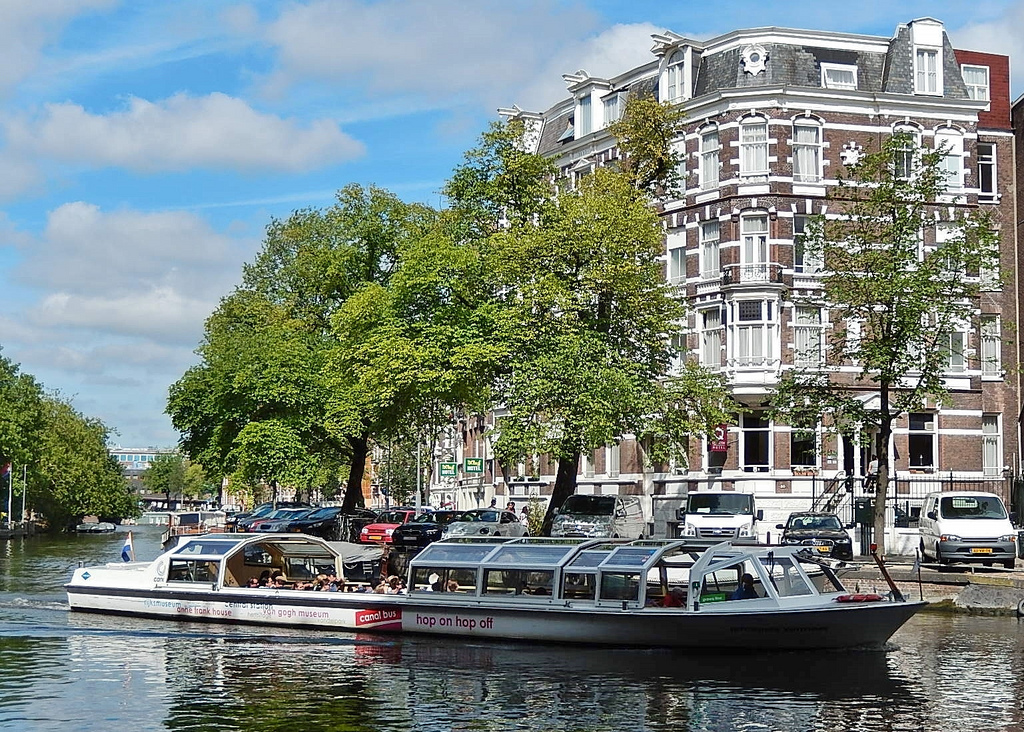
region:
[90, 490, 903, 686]
long white boat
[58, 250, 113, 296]
white clouds in blue sky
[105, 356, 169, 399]
white clouds in blue sky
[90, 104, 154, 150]
white clouds in blue sky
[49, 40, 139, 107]
white clouds in blue sky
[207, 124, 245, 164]
white clouds in blue sky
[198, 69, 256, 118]
white clouds in blue sky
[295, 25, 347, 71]
white clouds in blue sky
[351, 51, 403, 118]
white clouds in blue sky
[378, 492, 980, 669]
Boat on the water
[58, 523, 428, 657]
White boat on the water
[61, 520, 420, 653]
White boats on the water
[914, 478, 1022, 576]
Van is parked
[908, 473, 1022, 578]
White van is parked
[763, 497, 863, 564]
Black car is parked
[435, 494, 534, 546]
White car is parked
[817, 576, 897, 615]
Orange lifesaver on front of a boat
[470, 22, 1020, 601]
A large tall building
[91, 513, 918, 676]
A long tour boat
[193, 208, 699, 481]
Tall green trees along edge of water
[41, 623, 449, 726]
A canal of water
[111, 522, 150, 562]
A flag on back of boat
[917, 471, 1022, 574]
A white van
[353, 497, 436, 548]
A red car parked under tree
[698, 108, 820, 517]
A big brown building with white trim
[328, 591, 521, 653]
Red printed advertising on side of boat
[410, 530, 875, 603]
Boat has a glass covered top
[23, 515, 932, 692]
boats on the water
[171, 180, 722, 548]
trees are shading the cars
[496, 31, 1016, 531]
a large building with many windows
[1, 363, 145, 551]
trees near the river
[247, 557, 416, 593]
people on a boat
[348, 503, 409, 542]
a red car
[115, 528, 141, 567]
a flag on a boat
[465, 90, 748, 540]
large tall tree with green leaves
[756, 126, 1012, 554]
large tall tree with green leaves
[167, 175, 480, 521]
large tall tree with green leaves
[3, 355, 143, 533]
trees with green leaves beside the water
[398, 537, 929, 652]
long silver boat with red letters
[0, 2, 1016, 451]
light blue sky with white fluffy clouds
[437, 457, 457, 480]
green sign with white letters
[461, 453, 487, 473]
green sign with white letters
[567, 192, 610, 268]
green leaves on the tree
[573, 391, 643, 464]
green leaves on the tree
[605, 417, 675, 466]
green leaves on the tree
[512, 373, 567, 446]
green leaves on the tree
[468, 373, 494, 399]
green leaves on the tree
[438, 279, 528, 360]
green leaves on the tree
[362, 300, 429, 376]
green leaves on the tree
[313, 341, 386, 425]
green leaves on the tree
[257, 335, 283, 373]
green leaves on the tree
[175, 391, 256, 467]
green leaves on the tree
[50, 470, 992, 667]
boat on the water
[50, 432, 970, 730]
white boat on the water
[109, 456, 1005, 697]
people on the boat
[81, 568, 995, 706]
water in the background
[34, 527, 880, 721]
reflection on the water